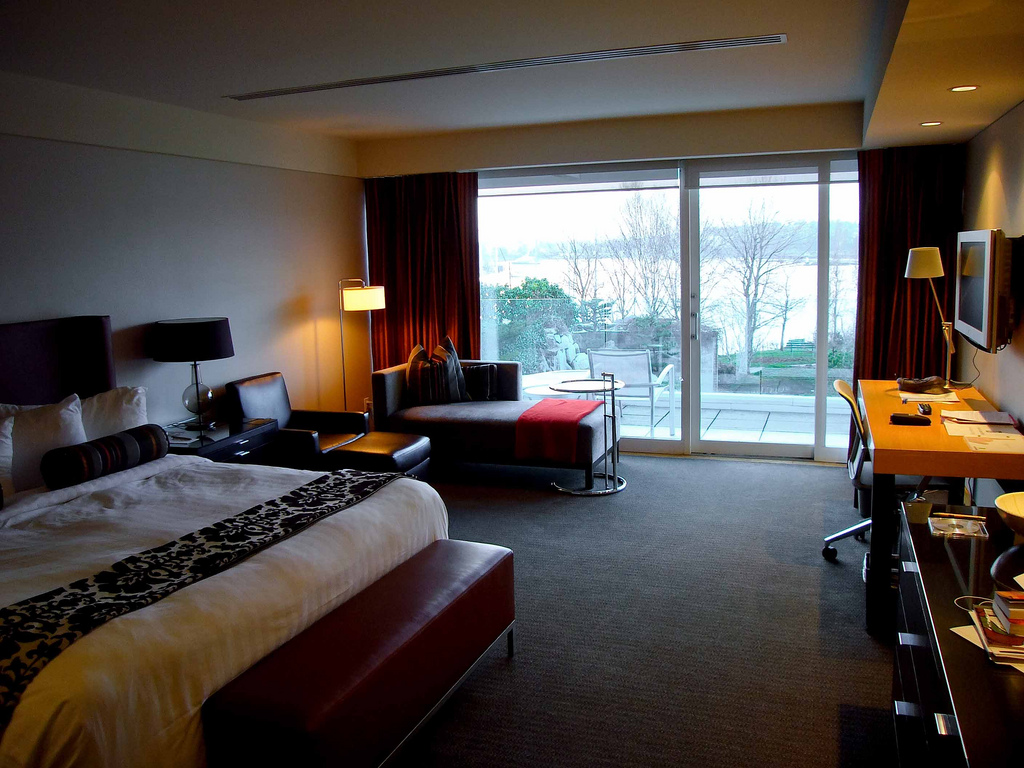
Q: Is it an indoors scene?
A: Yes, it is indoors.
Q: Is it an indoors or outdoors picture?
A: It is indoors.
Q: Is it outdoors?
A: No, it is indoors.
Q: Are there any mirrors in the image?
A: No, there are no mirrors.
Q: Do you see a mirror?
A: No, there are no mirrors.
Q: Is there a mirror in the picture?
A: No, there are no mirrors.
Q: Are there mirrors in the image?
A: No, there are no mirrors.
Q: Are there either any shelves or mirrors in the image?
A: No, there are no mirrors or shelves.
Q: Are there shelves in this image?
A: No, there are no shelves.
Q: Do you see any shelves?
A: No, there are no shelves.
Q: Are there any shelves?
A: No, there are no shelves.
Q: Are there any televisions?
A: Yes, there is a television.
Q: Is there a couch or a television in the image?
A: Yes, there is a television.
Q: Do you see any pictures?
A: No, there are no pictures.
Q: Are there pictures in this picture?
A: No, there are no pictures.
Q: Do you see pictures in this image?
A: No, there are no pictures.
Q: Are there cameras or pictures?
A: No, there are no pictures or cameras.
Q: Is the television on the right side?
A: Yes, the television is on the right of the image.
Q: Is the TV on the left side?
A: No, the TV is on the right of the image.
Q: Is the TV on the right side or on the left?
A: The TV is on the right of the image.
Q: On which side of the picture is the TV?
A: The TV is on the right of the image.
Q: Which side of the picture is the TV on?
A: The TV is on the right of the image.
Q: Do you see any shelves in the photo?
A: No, there are no shelves.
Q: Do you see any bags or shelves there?
A: No, there are no shelves or bags.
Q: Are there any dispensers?
A: No, there are no dispensers.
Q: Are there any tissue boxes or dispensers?
A: No, there are no dispensers or tissue boxes.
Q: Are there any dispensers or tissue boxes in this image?
A: No, there are no dispensers or tissue boxes.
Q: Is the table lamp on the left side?
A: Yes, the table lamp is on the left of the image.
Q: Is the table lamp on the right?
A: No, the table lamp is on the left of the image.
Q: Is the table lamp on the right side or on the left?
A: The table lamp is on the left of the image.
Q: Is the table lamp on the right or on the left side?
A: The table lamp is on the left of the image.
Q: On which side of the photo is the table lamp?
A: The table lamp is on the left of the image.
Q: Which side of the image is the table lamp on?
A: The table lamp is on the left of the image.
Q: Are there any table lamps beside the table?
A: Yes, there is a table lamp beside the table.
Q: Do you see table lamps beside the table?
A: Yes, there is a table lamp beside the table.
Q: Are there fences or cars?
A: No, there are no cars or fences.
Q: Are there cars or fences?
A: No, there are no cars or fences.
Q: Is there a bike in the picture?
A: No, there are no bikes.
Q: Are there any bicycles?
A: No, there are no bicycles.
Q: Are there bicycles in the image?
A: No, there are no bicycles.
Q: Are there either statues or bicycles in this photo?
A: No, there are no bicycles or statues.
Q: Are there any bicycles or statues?
A: No, there are no bicycles or statues.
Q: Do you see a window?
A: Yes, there is a window.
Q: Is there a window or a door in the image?
A: Yes, there is a window.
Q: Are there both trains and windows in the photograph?
A: No, there is a window but no trains.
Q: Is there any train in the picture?
A: No, there are no trains.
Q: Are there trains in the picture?
A: No, there are no trains.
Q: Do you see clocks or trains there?
A: No, there are no trains or clocks.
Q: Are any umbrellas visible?
A: No, there are no umbrellas.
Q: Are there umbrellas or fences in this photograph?
A: No, there are no umbrellas or fences.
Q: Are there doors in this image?
A: Yes, there is a door.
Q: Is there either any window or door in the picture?
A: Yes, there is a door.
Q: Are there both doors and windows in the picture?
A: Yes, there are both a door and windows.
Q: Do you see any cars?
A: No, there are no cars.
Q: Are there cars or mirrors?
A: No, there are no cars or mirrors.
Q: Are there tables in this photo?
A: Yes, there is a table.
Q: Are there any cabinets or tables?
A: Yes, there is a table.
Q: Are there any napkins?
A: No, there are no napkins.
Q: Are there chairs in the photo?
A: Yes, there is a chair.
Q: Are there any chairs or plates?
A: Yes, there is a chair.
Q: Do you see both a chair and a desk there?
A: Yes, there are both a chair and a desk.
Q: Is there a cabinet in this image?
A: No, there are no cabinets.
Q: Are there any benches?
A: Yes, there is a bench.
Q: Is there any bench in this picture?
A: Yes, there is a bench.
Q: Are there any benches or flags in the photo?
A: Yes, there is a bench.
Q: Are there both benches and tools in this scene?
A: No, there is a bench but no tools.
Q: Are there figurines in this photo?
A: No, there are no figurines.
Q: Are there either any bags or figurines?
A: No, there are no figurines or bags.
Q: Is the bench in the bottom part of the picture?
A: Yes, the bench is in the bottom of the image.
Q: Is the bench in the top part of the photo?
A: No, the bench is in the bottom of the image.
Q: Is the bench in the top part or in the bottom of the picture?
A: The bench is in the bottom of the image.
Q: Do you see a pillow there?
A: Yes, there is a pillow.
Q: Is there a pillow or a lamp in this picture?
A: Yes, there is a pillow.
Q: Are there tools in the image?
A: No, there are no tools.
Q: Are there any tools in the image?
A: No, there are no tools.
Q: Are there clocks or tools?
A: No, there are no tools or clocks.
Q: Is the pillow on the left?
A: Yes, the pillow is on the left of the image.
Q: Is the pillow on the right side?
A: No, the pillow is on the left of the image.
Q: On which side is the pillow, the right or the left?
A: The pillow is on the left of the image.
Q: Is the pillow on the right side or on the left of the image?
A: The pillow is on the left of the image.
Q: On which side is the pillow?
A: The pillow is on the left of the image.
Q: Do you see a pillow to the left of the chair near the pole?
A: Yes, there is a pillow to the left of the chair.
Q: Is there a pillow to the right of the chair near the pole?
A: No, the pillow is to the left of the chair.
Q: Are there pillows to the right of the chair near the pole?
A: No, the pillow is to the left of the chair.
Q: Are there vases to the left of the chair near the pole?
A: No, there is a pillow to the left of the chair.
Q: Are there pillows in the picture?
A: Yes, there are pillows.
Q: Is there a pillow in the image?
A: Yes, there are pillows.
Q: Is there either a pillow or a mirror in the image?
A: Yes, there are pillows.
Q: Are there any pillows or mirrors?
A: Yes, there are pillows.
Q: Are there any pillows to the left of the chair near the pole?
A: Yes, there are pillows to the left of the chair.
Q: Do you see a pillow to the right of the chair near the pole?
A: No, the pillows are to the left of the chair.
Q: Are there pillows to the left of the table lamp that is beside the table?
A: Yes, there are pillows to the left of the table lamp.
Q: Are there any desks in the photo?
A: Yes, there is a desk.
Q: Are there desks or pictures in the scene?
A: Yes, there is a desk.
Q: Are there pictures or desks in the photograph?
A: Yes, there is a desk.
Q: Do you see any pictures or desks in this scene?
A: Yes, there is a desk.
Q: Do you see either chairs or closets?
A: Yes, there is a chair.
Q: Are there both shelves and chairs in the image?
A: No, there is a chair but no shelves.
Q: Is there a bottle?
A: No, there are no bottles.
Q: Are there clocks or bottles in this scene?
A: No, there are no bottles or clocks.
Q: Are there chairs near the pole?
A: Yes, there is a chair near the pole.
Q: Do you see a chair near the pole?
A: Yes, there is a chair near the pole.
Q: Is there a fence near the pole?
A: No, there is a chair near the pole.